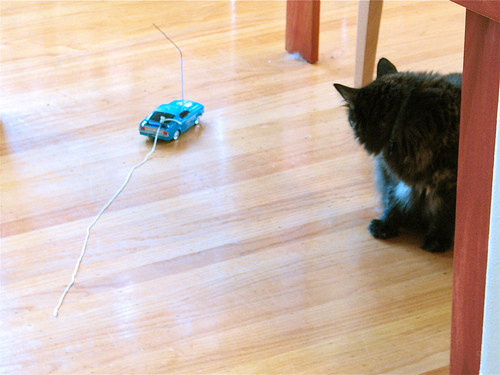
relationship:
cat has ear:
[332, 54, 462, 264] [324, 59, 378, 144]